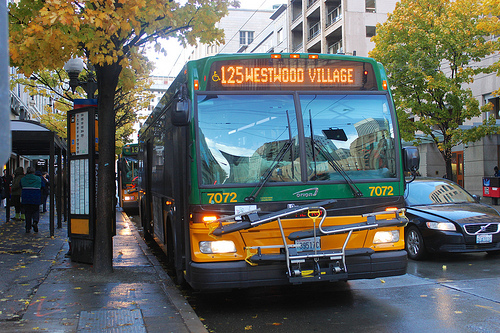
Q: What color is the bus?
A: Green and orange.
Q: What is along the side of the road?
A: Trees.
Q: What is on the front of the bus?
A: Bike rack.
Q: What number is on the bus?
A: 7072.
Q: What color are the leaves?
A: Yellow.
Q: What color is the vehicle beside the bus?
A: Black.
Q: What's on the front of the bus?
A: A bike rack.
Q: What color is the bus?
A: Green and yellow.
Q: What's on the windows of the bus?
A: Windshield wipers.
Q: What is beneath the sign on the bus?
A: A windshield.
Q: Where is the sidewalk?
A: A kiosk.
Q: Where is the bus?
A: On the street.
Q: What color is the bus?
A: Green and yellow.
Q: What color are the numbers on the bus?
A: Yellow.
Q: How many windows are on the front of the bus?
A: Two.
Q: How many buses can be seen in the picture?
A: Two.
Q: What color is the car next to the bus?
A: Black.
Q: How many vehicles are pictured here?
A: Three.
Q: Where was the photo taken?
A: The street.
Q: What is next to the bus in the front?
A: A car.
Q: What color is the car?
A: Black.